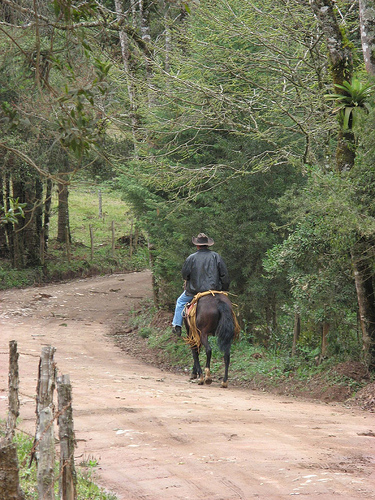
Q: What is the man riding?
A: Horse.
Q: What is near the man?
A: Fence.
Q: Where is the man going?
A: Down a dirt road.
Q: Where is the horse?
A: Dirt road.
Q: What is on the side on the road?
A: Trees.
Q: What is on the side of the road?
A: Grass.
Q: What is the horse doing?
A: Trotting.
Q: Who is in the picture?
A: A man.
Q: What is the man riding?
A: A horse.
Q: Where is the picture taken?
A: A park.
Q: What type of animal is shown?
A: A horse.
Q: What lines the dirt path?
A: Trees.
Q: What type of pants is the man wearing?
A: Jeans.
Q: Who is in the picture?
A: A man.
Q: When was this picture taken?
A: Daytime.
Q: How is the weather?
A: Clear.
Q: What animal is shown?
A: A horse.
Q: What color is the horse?
A: Brown.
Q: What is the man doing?
A: Riding a horse.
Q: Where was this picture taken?
A: A park.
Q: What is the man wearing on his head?
A: Hat.